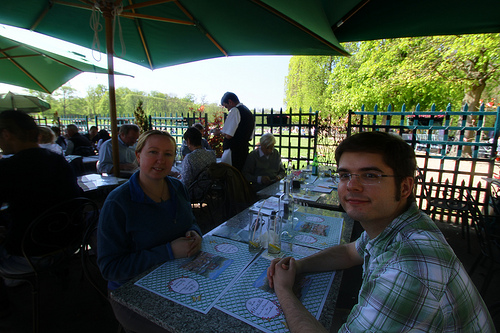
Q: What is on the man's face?
A: Glasses.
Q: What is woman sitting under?
A: Umbrella.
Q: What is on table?
A: Place mat.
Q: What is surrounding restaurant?
A: Fence.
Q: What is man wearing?
A: Plaid shirt.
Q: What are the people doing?
A: Waiting for food.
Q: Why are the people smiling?
A: To take a picture.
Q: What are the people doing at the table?
A: Sitting.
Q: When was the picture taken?
A: During the day.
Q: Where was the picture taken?
A: At a restaurant.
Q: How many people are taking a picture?
A: Two.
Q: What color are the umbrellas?
A: Green.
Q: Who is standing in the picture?
A: A waiter.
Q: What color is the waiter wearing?
A: Black and white.